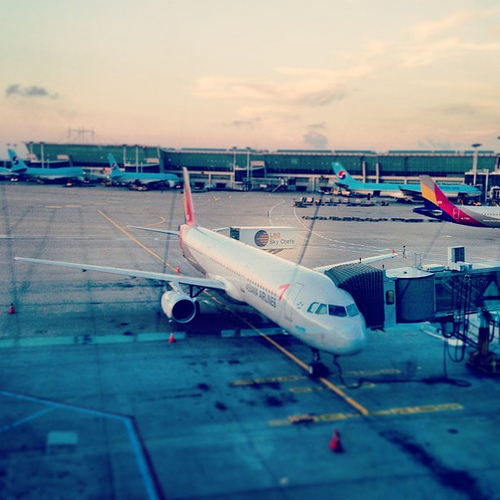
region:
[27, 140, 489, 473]
airplanes on the road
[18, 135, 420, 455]
airplane at airport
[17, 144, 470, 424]
a white airplane on the ground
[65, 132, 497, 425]
a white airplane at airport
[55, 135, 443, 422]
white airplane with red tail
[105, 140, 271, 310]
a red airplane tail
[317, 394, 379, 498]
a cone on the ground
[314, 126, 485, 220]
a blue pepsi airplane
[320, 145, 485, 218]
a blue pepsi plane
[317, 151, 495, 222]
a pepsi plane at airport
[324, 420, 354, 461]
orange caution cone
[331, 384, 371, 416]
yellow lines on the pavement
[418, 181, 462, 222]
the colorful tail fin on the plane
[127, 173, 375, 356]
a large commercial plane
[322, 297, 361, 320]
windshield of a plane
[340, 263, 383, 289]
a black accordion connector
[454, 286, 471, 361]
black cords hanging down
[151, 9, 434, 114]
a white sky overhead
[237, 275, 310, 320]
a company name on the plane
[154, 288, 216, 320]
an engine under the wing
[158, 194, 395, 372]
a fuselage on a tarmac.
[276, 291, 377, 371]
a large cock pit.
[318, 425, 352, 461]
a small orange cone.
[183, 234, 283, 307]
a row of windows.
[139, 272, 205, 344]
a large jet engine.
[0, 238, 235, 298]
a right jet wing.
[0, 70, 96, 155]
a cloud in a pink sky.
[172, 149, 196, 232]
a wing on the back of a jet.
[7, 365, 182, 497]
a line on a tarmac.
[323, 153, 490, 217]
a large blue jet.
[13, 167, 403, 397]
plane docked at gate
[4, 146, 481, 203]
three blue planes in background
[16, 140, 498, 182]
airport gates in background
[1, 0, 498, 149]
clouds in a colorful sky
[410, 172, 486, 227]
blue, yellow and red tail fin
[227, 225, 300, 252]
truck behind plane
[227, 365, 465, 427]
yellow writing on ground in front of plane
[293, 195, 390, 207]
baggage cars near blue plane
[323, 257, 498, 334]
gate attached to plane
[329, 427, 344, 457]
orange cone in front of plane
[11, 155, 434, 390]
A white jet waiting for passengers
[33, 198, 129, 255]
A gray concrete surface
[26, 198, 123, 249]
An airport tarmac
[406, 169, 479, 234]
The tail of a jet with the colors red, yellow and blue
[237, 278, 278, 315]
Black printing on the side of a jet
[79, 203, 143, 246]
A yellow line painted on the tarmac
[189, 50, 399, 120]
White clouds in the sky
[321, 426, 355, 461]
An orange traffic cone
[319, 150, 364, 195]
A blue plane's tail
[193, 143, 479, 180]
Airport terminal building